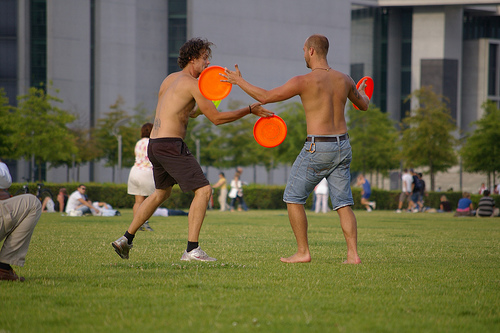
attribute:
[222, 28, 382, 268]
man — shoeless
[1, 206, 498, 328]
field — large, green, grassy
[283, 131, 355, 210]
shorts — blue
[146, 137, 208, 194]
shorts — black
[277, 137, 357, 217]
shorts — blue, denim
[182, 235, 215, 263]
shoes — silver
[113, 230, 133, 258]
shoes — silver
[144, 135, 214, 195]
shorts — dark gray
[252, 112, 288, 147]
frisbee — circular, orange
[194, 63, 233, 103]
frisbee — orange, plastic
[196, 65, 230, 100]
frisbee — orange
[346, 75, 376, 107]
frisbee — orange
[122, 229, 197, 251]
socks — black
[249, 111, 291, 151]
frisbee — orange, plastic, circular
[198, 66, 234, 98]
frisbee — orange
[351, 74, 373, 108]
frisbee — orange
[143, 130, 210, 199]
shorts — black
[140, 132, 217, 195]
shorts — maroon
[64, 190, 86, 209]
shirt — white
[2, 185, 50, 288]
pants — beige